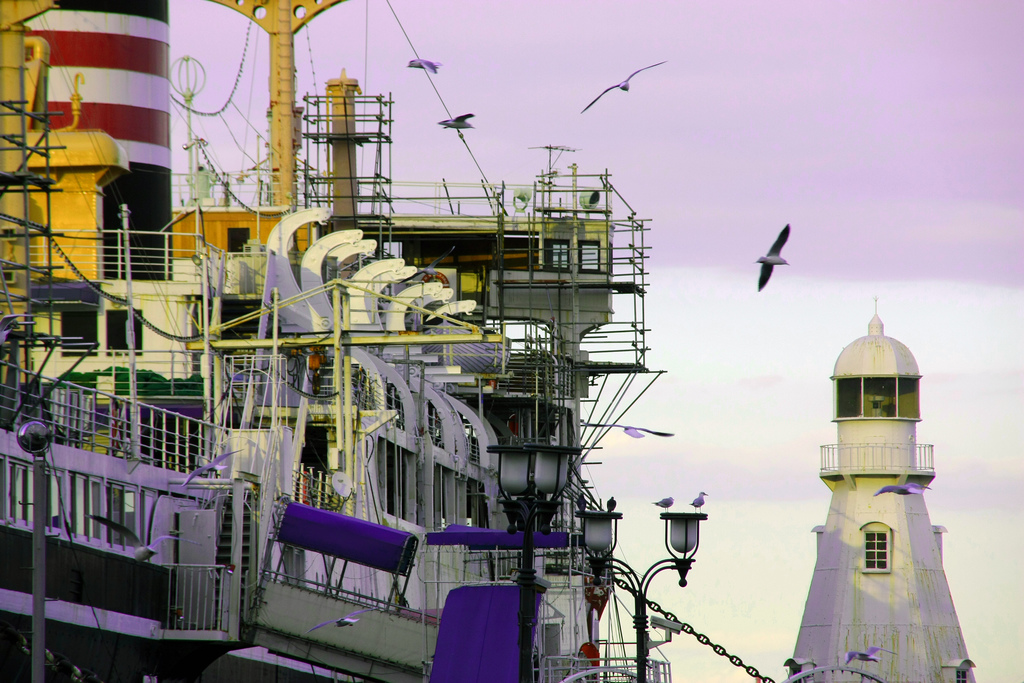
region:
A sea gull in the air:
[750, 221, 796, 294]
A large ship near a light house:
[5, 3, 676, 678]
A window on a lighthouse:
[860, 519, 895, 568]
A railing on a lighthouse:
[816, 440, 934, 473]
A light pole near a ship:
[570, 509, 710, 671]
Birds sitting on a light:
[653, 480, 711, 519]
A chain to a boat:
[593, 552, 791, 677]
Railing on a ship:
[5, 354, 230, 482]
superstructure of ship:
[4, 0, 656, 576]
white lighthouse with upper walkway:
[791, 295, 987, 679]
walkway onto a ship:
[2, 419, 437, 672]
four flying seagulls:
[401, 42, 793, 305]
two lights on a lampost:
[570, 505, 707, 679]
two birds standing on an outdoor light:
[650, 485, 718, 591]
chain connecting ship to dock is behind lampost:
[2, 2, 780, 679]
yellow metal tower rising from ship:
[4, 5, 662, 679]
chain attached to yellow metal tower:
[173, 2, 347, 209]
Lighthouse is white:
[781, 297, 975, 680]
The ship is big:
[0, 2, 671, 680]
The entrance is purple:
[277, 503, 576, 680]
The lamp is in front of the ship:
[576, 509, 707, 680]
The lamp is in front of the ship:
[484, 439, 579, 680]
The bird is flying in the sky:
[574, 55, 670, 119]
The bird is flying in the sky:
[435, 109, 475, 130]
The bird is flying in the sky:
[403, 54, 442, 75]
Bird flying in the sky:
[743, 221, 811, 302]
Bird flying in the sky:
[562, 50, 676, 117]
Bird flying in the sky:
[422, 97, 486, 158]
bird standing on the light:
[683, 478, 719, 521]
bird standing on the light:
[648, 489, 683, 510]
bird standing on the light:
[604, 492, 615, 511]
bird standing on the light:
[559, 483, 594, 522]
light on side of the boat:
[16, 410, 48, 448]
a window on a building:
[833, 382, 857, 417]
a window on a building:
[898, 374, 921, 419]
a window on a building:
[588, 237, 604, 266]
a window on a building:
[119, 491, 152, 543]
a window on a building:
[538, 241, 559, 268]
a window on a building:
[58, 304, 94, 366]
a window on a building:
[106, 304, 146, 361]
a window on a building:
[221, 213, 256, 246]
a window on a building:
[835, 371, 861, 420]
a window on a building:
[864, 509, 885, 577]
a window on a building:
[356, 356, 373, 410]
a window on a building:
[383, 381, 407, 414]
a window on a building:
[424, 397, 451, 443]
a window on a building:
[459, 408, 482, 459]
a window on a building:
[64, 308, 94, 347]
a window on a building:
[103, 299, 142, 329]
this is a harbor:
[43, 85, 844, 630]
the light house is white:
[687, 193, 1000, 582]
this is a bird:
[710, 171, 832, 346]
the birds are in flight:
[568, 13, 919, 415]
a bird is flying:
[716, 197, 827, 281]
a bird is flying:
[582, 63, 678, 124]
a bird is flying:
[421, 113, 494, 171]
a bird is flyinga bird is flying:
[342, 22, 467, 121]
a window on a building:
[866, 379, 898, 411]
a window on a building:
[239, 183, 309, 294]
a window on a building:
[831, 374, 860, 413]